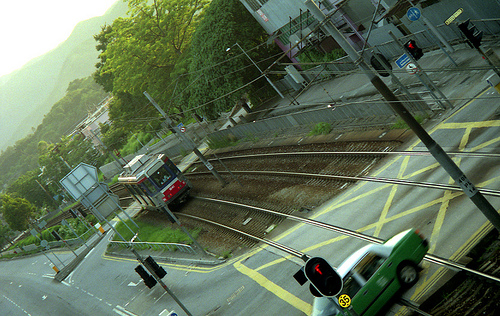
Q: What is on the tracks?
A: A train.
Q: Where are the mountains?
A: Outside of the city.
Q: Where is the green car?
A: Driving over the tracks.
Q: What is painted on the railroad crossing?
A: Yellow lines.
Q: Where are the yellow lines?
A: On the railroad crossing.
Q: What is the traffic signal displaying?
A: Red.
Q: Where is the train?
A: On the track.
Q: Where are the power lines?
A: Over the tracks.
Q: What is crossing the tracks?
A: A taxi.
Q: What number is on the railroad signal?
A: 35.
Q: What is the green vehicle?
A: A taxi.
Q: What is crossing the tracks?
A: A green and white car.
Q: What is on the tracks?
A: A trolley.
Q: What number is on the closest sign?
A: 35.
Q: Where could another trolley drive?
A: On the other set of tracks.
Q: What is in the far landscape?
A: Mountains.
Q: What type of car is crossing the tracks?
A: A taxi.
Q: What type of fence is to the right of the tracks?
A: A chain link fence.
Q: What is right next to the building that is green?
A: A tree.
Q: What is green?
A: Car.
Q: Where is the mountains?
A: Behind the train.